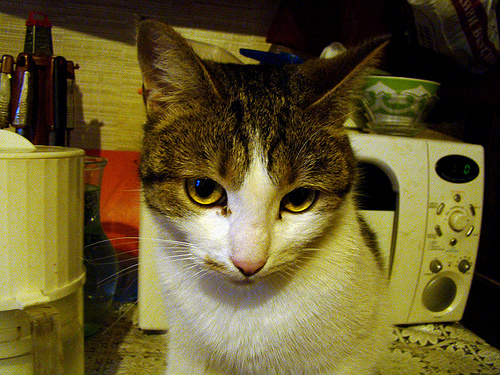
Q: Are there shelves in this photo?
A: No, there are no shelves.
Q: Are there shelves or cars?
A: No, there are no shelves or cars.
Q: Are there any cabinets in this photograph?
A: No, there are no cabinets.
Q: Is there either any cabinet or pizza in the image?
A: No, there are no cabinets or pizzas.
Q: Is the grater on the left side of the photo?
A: Yes, the grater is on the left of the image.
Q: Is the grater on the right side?
A: No, the grater is on the left of the image.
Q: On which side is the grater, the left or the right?
A: The grater is on the left of the image.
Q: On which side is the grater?
A: The grater is on the left of the image.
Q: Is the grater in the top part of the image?
A: Yes, the grater is in the top of the image.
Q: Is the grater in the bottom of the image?
A: No, the grater is in the top of the image.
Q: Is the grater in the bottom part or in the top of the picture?
A: The grater is in the top of the image.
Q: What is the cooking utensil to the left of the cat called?
A: The cooking utensil is a grater.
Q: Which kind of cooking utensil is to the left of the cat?
A: The cooking utensil is a grater.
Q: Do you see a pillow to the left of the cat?
A: No, there is a grater to the left of the cat.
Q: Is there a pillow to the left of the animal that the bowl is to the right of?
A: No, there is a grater to the left of the cat.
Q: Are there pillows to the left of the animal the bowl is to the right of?
A: No, there is a grater to the left of the cat.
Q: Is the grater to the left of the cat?
A: Yes, the grater is to the left of the cat.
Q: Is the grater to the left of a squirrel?
A: No, the grater is to the left of the cat.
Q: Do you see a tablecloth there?
A: Yes, there is a tablecloth.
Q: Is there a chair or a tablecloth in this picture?
A: Yes, there is a tablecloth.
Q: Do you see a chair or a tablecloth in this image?
A: Yes, there is a tablecloth.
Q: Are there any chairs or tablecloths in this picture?
A: Yes, there is a tablecloth.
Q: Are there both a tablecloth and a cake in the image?
A: No, there is a tablecloth but no cakes.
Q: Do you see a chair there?
A: No, there are no chairs.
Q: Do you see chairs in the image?
A: No, there are no chairs.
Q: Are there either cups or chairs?
A: No, there are no chairs or cups.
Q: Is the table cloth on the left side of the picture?
A: No, the table cloth is on the right of the image.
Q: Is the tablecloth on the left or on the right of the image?
A: The tablecloth is on the right of the image.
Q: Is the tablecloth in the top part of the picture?
A: No, the tablecloth is in the bottom of the image.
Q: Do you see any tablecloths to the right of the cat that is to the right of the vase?
A: Yes, there is a tablecloth to the right of the cat.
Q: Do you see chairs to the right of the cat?
A: No, there is a tablecloth to the right of the cat.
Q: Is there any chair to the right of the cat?
A: No, there is a tablecloth to the right of the cat.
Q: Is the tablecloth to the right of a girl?
A: No, the tablecloth is to the right of the cat.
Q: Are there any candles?
A: No, there are no candles.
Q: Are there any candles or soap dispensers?
A: No, there are no candles or soap dispensers.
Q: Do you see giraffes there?
A: No, there are no giraffes.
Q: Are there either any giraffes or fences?
A: No, there are no giraffes or fences.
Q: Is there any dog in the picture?
A: No, there are no dogs.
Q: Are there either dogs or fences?
A: No, there are no dogs or fences.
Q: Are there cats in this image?
A: Yes, there is a cat.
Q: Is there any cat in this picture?
A: Yes, there is a cat.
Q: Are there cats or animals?
A: Yes, there is a cat.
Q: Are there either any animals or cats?
A: Yes, there is a cat.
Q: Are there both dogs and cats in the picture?
A: No, there is a cat but no dogs.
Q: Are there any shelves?
A: No, there are no shelves.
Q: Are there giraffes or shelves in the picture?
A: No, there are no shelves or giraffes.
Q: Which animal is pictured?
A: The animal is a cat.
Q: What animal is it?
A: The animal is a cat.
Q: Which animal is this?
A: This is a cat.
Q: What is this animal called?
A: This is a cat.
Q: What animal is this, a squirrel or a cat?
A: This is a cat.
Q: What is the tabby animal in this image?
A: The animal is a cat.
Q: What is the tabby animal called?
A: The animal is a cat.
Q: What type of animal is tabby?
A: The animal is a cat.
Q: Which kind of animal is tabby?
A: The animal is a cat.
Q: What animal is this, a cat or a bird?
A: This is a cat.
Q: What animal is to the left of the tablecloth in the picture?
A: The animal is a cat.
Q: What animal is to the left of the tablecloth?
A: The animal is a cat.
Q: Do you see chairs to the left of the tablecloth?
A: No, there is a cat to the left of the tablecloth.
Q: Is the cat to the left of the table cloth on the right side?
A: Yes, the cat is to the left of the tablecloth.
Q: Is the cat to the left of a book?
A: No, the cat is to the left of the tablecloth.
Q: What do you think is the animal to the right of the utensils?
A: The animal is a cat.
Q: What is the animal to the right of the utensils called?
A: The animal is a cat.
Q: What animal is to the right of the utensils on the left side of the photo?
A: The animal is a cat.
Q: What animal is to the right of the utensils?
A: The animal is a cat.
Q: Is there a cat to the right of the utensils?
A: Yes, there is a cat to the right of the utensils.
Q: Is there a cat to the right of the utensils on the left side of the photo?
A: Yes, there is a cat to the right of the utensils.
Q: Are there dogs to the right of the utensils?
A: No, there is a cat to the right of the utensils.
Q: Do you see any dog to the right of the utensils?
A: No, there is a cat to the right of the utensils.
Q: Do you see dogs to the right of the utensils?
A: No, there is a cat to the right of the utensils.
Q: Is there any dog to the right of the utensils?
A: No, there is a cat to the right of the utensils.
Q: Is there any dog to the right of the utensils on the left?
A: No, there is a cat to the right of the utensils.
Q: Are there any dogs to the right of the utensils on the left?
A: No, there is a cat to the right of the utensils.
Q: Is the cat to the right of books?
A: No, the cat is to the right of the utensils.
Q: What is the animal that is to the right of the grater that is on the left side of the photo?
A: The animal is a cat.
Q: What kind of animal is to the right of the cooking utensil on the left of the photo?
A: The animal is a cat.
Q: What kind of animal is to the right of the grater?
A: The animal is a cat.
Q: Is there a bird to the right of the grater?
A: No, there is a cat to the right of the grater.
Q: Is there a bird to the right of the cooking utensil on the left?
A: No, there is a cat to the right of the grater.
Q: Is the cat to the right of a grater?
A: Yes, the cat is to the right of a grater.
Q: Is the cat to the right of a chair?
A: No, the cat is to the right of a grater.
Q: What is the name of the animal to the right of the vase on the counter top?
A: The animal is a cat.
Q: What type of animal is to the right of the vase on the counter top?
A: The animal is a cat.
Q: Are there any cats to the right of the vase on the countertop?
A: Yes, there is a cat to the right of the vase.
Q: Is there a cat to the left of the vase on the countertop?
A: No, the cat is to the right of the vase.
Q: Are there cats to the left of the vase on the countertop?
A: No, the cat is to the right of the vase.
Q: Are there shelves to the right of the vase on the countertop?
A: No, there is a cat to the right of the vase.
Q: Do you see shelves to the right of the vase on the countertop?
A: No, there is a cat to the right of the vase.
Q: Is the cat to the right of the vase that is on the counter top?
A: Yes, the cat is to the right of the vase.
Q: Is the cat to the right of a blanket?
A: No, the cat is to the right of the vase.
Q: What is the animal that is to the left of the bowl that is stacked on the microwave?
A: The animal is a cat.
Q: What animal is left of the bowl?
A: The animal is a cat.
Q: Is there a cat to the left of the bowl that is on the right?
A: Yes, there is a cat to the left of the bowl.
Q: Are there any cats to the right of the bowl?
A: No, the cat is to the left of the bowl.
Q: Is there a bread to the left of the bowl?
A: No, there is a cat to the left of the bowl.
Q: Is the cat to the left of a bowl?
A: Yes, the cat is to the left of a bowl.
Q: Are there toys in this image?
A: No, there are no toys.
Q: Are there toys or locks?
A: No, there are no toys or locks.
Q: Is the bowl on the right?
A: Yes, the bowl is on the right of the image.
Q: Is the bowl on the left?
A: No, the bowl is on the right of the image.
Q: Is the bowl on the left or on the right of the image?
A: The bowl is on the right of the image.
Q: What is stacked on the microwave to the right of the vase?
A: The bowl is stacked on the microwave.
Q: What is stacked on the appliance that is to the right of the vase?
A: The bowl is stacked on the microwave.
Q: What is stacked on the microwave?
A: The bowl is stacked on the microwave.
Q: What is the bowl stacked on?
A: The bowl is stacked on the microwave.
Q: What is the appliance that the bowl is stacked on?
A: The appliance is a microwave.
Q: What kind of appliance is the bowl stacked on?
A: The bowl is stacked on the microwave.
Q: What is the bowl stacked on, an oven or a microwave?
A: The bowl is stacked on a microwave.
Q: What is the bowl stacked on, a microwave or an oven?
A: The bowl is stacked on a microwave.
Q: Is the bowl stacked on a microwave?
A: Yes, the bowl is stacked on a microwave.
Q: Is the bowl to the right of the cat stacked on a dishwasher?
A: No, the bowl is stacked on a microwave.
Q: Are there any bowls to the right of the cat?
A: Yes, there is a bowl to the right of the cat.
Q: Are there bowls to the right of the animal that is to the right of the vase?
A: Yes, there is a bowl to the right of the cat.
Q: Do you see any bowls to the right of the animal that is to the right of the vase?
A: Yes, there is a bowl to the right of the cat.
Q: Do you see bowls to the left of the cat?
A: No, the bowl is to the right of the cat.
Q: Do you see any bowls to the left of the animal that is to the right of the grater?
A: No, the bowl is to the right of the cat.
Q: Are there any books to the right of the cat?
A: No, there is a bowl to the right of the cat.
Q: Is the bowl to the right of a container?
A: No, the bowl is to the right of the cat.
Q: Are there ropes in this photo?
A: No, there are no ropes.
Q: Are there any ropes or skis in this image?
A: No, there are no ropes or skis.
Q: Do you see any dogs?
A: No, there are no dogs.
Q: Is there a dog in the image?
A: No, there are no dogs.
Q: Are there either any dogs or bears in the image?
A: No, there are no dogs or bears.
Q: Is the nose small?
A: Yes, the nose is small.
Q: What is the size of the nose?
A: The nose is small.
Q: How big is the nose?
A: The nose is small.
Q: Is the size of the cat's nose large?
A: No, the nose is small.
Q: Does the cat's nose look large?
A: No, the nose is small.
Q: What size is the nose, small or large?
A: The nose is small.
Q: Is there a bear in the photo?
A: No, there are no bears.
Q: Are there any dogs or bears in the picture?
A: No, there are no bears or dogs.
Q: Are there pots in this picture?
A: No, there are no pots.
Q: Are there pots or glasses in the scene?
A: No, there are no pots or glasses.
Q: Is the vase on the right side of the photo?
A: No, the vase is on the left of the image.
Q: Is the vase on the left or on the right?
A: The vase is on the left of the image.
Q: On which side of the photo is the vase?
A: The vase is on the left of the image.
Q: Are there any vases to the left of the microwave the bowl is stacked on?
A: Yes, there is a vase to the left of the microwave.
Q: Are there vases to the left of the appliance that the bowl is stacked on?
A: Yes, there is a vase to the left of the microwave.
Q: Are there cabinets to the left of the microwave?
A: No, there is a vase to the left of the microwave.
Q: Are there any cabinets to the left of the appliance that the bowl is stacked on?
A: No, there is a vase to the left of the microwave.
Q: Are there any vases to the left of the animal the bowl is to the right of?
A: Yes, there is a vase to the left of the cat.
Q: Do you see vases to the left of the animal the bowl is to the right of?
A: Yes, there is a vase to the left of the cat.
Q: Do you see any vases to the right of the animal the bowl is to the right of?
A: No, the vase is to the left of the cat.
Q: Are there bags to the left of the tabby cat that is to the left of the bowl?
A: No, there is a vase to the left of the cat.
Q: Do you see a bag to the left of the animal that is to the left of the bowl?
A: No, there is a vase to the left of the cat.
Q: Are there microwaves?
A: Yes, there is a microwave.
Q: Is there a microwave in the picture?
A: Yes, there is a microwave.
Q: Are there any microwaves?
A: Yes, there is a microwave.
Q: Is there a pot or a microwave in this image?
A: Yes, there is a microwave.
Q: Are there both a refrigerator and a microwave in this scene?
A: No, there is a microwave but no refrigerators.